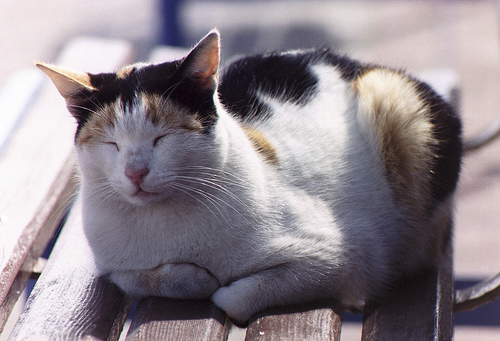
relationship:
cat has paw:
[32, 27, 470, 322] [115, 260, 217, 302]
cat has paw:
[32, 27, 470, 322] [212, 280, 259, 327]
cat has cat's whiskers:
[32, 27, 470, 322] [152, 163, 264, 229]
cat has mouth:
[32, 27, 470, 322] [121, 176, 152, 201]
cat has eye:
[32, 27, 470, 322] [151, 132, 171, 147]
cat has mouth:
[32, 27, 470, 322] [128, 188, 160, 200]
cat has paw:
[32, 27, 470, 322] [145, 261, 219, 300]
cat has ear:
[32, 27, 470, 322] [32, 46, 111, 136]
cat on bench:
[37, 62, 470, 323] [42, 288, 463, 338]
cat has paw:
[32, 27, 470, 322] [125, 241, 220, 301]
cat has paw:
[32, 27, 470, 322] [206, 265, 271, 322]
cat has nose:
[32, 27, 470, 322] [116, 153, 153, 185]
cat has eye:
[32, 27, 470, 322] [101, 136, 121, 151]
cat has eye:
[32, 27, 470, 322] [152, 128, 177, 151]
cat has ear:
[32, 27, 470, 322] [36, 63, 91, 103]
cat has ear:
[32, 27, 470, 322] [180, 28, 220, 85]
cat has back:
[32, 27, 470, 322] [208, 47, 377, 181]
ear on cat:
[30, 58, 97, 111] [32, 27, 470, 322]